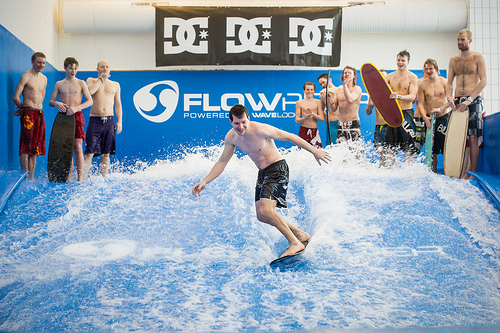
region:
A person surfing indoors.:
[190, 105, 332, 265]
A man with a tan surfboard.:
[443, 28, 487, 181]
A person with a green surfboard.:
[416, 56, 451, 173]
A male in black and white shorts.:
[330, 63, 363, 144]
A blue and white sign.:
[109, 69, 342, 173]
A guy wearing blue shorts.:
[83, 58, 121, 180]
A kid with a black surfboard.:
[43, 57, 84, 184]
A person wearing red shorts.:
[11, 50, 48, 180]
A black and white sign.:
[154, 4, 344, 69]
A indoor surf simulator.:
[1, 137, 499, 332]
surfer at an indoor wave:
[181, 100, 340, 282]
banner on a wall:
[144, 14, 348, 65]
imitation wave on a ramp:
[312, 172, 415, 300]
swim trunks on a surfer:
[253, 160, 297, 207]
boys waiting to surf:
[18, 49, 148, 184]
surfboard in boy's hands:
[43, 106, 78, 201]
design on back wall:
[122, 74, 190, 124]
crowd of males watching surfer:
[293, 33, 484, 180]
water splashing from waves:
[341, 133, 401, 169]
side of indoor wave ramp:
[6, 150, 36, 237]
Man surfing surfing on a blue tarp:
[177, 100, 332, 265]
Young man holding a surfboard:
[45, 51, 90, 178]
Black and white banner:
[151, 0, 341, 65]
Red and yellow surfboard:
[360, 60, 405, 126]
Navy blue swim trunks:
[250, 157, 290, 207]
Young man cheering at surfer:
[327, 65, 371, 140]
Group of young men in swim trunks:
[293, 24, 499, 184]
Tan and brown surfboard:
[441, 106, 471, 179]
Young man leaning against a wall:
[9, 48, 54, 180]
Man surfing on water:
[188, 99, 340, 266]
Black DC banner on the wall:
[154, 5, 341, 67]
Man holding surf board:
[440, 23, 487, 186]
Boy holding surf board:
[46, 55, 88, 183]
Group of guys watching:
[10, 50, 123, 180]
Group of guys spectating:
[300, 26, 497, 176]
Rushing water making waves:
[92, 143, 443, 331]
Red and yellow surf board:
[357, 59, 407, 126]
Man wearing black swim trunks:
[190, 102, 337, 269]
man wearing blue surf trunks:
[82, 58, 127, 183]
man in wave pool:
[189, 96, 339, 267]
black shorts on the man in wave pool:
[242, 152, 291, 210]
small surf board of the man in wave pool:
[268, 232, 315, 269]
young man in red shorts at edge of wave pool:
[12, 49, 50, 184]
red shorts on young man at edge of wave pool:
[17, 104, 47, 159]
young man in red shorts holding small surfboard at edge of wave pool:
[48, 53, 88, 182]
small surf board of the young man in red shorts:
[45, 102, 77, 183]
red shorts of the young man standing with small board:
[72, 110, 86, 137]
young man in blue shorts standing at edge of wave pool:
[87, 58, 124, 173]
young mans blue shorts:
[83, 113, 120, 158]